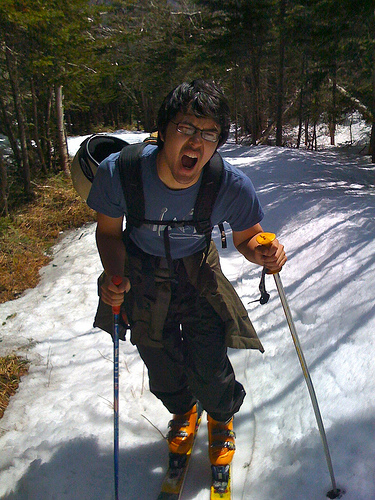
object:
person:
[93, 76, 286, 470]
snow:
[0, 217, 116, 499]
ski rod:
[108, 272, 125, 498]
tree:
[51, 0, 72, 182]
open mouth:
[179, 152, 196, 174]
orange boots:
[165, 405, 202, 456]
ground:
[0, 114, 374, 499]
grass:
[0, 155, 98, 303]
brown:
[0, 353, 28, 420]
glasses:
[170, 118, 223, 146]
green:
[0, 213, 11, 238]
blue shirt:
[86, 140, 265, 259]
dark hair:
[155, 80, 232, 150]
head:
[157, 80, 232, 188]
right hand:
[96, 269, 131, 311]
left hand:
[258, 233, 285, 275]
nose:
[188, 128, 203, 150]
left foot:
[204, 413, 235, 471]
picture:
[0, 0, 374, 499]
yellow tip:
[255, 232, 277, 245]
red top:
[110, 275, 123, 319]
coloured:
[113, 344, 119, 366]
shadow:
[252, 257, 374, 339]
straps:
[119, 141, 148, 234]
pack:
[117, 128, 226, 279]